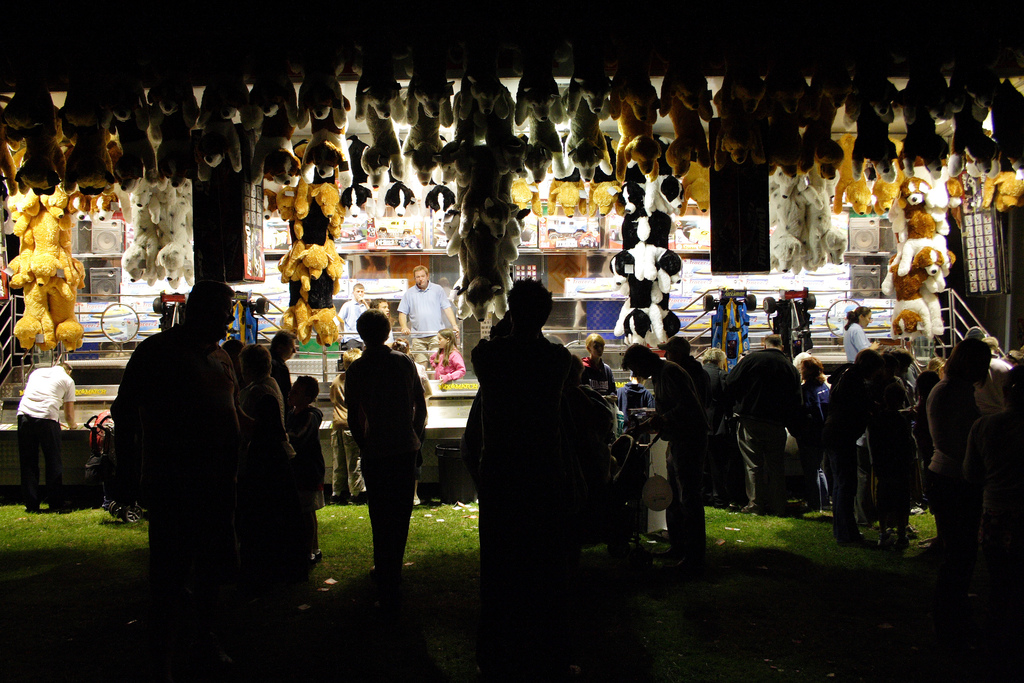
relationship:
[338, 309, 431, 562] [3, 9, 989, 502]
person standing in front of booth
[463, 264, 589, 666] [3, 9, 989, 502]
person standing in front of booth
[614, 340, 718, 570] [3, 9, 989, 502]
person standing in front of booth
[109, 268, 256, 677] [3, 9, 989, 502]
person standing in front of booth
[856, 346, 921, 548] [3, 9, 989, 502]
person standing in front of booth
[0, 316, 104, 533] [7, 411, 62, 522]
man wearing pants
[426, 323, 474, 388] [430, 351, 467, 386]
girl in sweatshirt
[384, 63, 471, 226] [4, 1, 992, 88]
plushes from roof